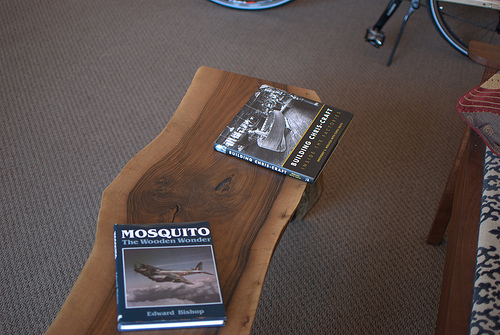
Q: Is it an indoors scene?
A: Yes, it is indoors.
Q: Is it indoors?
A: Yes, it is indoors.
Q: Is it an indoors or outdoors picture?
A: It is indoors.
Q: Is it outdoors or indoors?
A: It is indoors.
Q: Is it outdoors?
A: No, it is indoors.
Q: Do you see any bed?
A: No, there are no beds.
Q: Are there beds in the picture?
A: No, there are no beds.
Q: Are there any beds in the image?
A: No, there are no beds.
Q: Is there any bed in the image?
A: No, there are no beds.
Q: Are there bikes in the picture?
A: Yes, there is a bike.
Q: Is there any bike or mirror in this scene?
A: Yes, there is a bike.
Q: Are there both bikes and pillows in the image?
A: Yes, there are both a bike and a pillow.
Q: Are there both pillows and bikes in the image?
A: Yes, there are both a bike and a pillow.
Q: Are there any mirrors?
A: No, there are no mirrors.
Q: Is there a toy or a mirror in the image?
A: No, there are no mirrors or toys.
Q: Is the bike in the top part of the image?
A: Yes, the bike is in the top of the image.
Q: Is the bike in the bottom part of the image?
A: No, the bike is in the top of the image.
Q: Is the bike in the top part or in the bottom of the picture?
A: The bike is in the top of the image.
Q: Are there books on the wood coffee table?
A: Yes, there is a book on the coffee table.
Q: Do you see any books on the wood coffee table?
A: Yes, there is a book on the coffee table.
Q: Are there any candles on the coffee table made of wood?
A: No, there is a book on the coffee table.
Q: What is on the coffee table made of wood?
A: The book is on the coffee table.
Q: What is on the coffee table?
A: The book is on the coffee table.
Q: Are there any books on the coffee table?
A: Yes, there is a book on the coffee table.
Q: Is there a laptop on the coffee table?
A: No, there is a book on the coffee table.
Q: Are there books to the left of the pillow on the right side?
A: Yes, there is a book to the left of the pillow.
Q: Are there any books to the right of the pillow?
A: No, the book is to the left of the pillow.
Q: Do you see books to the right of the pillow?
A: No, the book is to the left of the pillow.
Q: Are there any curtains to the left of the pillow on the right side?
A: No, there is a book to the left of the pillow.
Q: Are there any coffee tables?
A: Yes, there is a coffee table.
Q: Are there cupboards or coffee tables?
A: Yes, there is a coffee table.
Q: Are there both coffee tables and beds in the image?
A: No, there is a coffee table but no beds.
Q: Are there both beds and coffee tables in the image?
A: No, there is a coffee table but no beds.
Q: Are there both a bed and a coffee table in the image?
A: No, there is a coffee table but no beds.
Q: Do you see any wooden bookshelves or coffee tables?
A: Yes, there is a wood coffee table.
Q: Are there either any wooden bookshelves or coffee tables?
A: Yes, there is a wood coffee table.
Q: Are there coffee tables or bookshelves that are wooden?
A: Yes, the coffee table is wooden.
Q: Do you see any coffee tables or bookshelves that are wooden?
A: Yes, the coffee table is wooden.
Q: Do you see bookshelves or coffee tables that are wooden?
A: Yes, the coffee table is wooden.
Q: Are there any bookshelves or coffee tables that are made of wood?
A: Yes, the coffee table is made of wood.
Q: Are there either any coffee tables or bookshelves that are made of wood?
A: Yes, the coffee table is made of wood.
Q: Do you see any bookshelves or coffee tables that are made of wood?
A: Yes, the coffee table is made of wood.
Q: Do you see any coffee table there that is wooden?
A: Yes, there is a wood coffee table.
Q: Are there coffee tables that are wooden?
A: Yes, there is a coffee table that is wooden.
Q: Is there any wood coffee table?
A: Yes, there is a coffee table that is made of wood.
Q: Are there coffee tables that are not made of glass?
A: Yes, there is a coffee table that is made of wood.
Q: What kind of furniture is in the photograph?
A: The furniture is a coffee table.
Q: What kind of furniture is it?
A: The piece of furniture is a coffee table.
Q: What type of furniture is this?
A: This is a coffee table.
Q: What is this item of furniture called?
A: This is a coffee table.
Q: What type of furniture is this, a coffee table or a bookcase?
A: This is a coffee table.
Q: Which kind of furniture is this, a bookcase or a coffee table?
A: This is a coffee table.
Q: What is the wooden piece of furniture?
A: The piece of furniture is a coffee table.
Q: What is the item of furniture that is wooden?
A: The piece of furniture is a coffee table.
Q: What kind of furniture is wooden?
A: The furniture is a coffee table.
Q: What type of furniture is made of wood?
A: The furniture is a coffee table.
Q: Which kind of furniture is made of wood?
A: The furniture is a coffee table.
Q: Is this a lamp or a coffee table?
A: This is a coffee table.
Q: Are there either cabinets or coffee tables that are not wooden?
A: No, there is a coffee table but it is wooden.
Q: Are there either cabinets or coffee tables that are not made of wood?
A: No, there is a coffee table but it is made of wood.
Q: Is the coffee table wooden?
A: Yes, the coffee table is wooden.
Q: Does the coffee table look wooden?
A: Yes, the coffee table is wooden.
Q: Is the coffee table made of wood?
A: Yes, the coffee table is made of wood.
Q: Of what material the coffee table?
A: The coffee table is made of wood.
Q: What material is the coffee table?
A: The coffee table is made of wood.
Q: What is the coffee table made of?
A: The coffee table is made of wood.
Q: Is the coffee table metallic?
A: No, the coffee table is wooden.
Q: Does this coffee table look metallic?
A: No, the coffee table is wooden.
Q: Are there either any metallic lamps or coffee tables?
A: No, there is a coffee table but it is wooden.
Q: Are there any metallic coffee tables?
A: No, there is a coffee table but it is wooden.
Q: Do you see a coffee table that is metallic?
A: No, there is a coffee table but it is wooden.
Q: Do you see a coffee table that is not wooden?
A: No, there is a coffee table but it is wooden.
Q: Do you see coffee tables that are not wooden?
A: No, there is a coffee table but it is wooden.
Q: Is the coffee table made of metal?
A: No, the coffee table is made of wood.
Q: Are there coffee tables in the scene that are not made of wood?
A: No, there is a coffee table but it is made of wood.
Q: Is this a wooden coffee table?
A: Yes, this is a wooden coffee table.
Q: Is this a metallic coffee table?
A: No, this is a wooden coffee table.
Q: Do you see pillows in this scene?
A: Yes, there is a pillow.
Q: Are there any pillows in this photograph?
A: Yes, there is a pillow.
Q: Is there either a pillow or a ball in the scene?
A: Yes, there is a pillow.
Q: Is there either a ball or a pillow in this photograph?
A: Yes, there is a pillow.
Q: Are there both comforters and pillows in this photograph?
A: No, there is a pillow but no comforters.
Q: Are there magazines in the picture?
A: No, there are no magazines.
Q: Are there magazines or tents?
A: No, there are no magazines or tents.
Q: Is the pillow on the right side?
A: Yes, the pillow is on the right of the image.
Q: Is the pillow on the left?
A: No, the pillow is on the right of the image.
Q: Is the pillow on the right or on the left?
A: The pillow is on the right of the image.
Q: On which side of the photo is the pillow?
A: The pillow is on the right of the image.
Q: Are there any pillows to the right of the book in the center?
A: Yes, there is a pillow to the right of the book.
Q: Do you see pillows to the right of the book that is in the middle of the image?
A: Yes, there is a pillow to the right of the book.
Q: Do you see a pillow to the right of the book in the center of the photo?
A: Yes, there is a pillow to the right of the book.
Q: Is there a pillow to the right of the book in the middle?
A: Yes, there is a pillow to the right of the book.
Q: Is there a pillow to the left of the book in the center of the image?
A: No, the pillow is to the right of the book.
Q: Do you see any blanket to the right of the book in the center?
A: No, there is a pillow to the right of the book.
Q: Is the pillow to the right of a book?
A: Yes, the pillow is to the right of a book.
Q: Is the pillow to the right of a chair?
A: No, the pillow is to the right of a book.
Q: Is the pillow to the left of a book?
A: No, the pillow is to the right of a book.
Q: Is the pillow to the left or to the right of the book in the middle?
A: The pillow is to the right of the book.